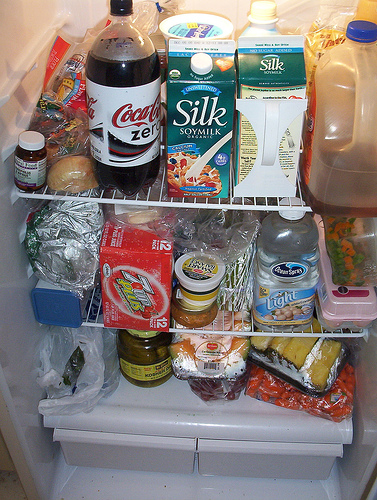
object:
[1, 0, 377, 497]
picture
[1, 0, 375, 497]
fridge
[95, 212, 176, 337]
7 up box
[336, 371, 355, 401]
baby carrot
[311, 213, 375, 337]
egg case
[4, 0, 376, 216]
top rack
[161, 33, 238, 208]
soy milk carton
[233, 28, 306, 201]
soy milk carton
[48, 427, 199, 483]
drawer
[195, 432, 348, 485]
drawer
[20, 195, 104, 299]
foil bag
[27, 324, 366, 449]
bottom rack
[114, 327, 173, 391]
pickle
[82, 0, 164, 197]
coca cola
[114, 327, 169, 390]
jar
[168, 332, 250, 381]
cantaloupe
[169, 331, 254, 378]
package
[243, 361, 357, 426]
bag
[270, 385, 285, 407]
baby carrot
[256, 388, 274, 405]
baby carrot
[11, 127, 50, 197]
bottle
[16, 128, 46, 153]
cap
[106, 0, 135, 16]
cap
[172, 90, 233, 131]
silk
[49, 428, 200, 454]
handle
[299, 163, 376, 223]
tea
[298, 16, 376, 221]
jug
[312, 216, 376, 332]
eggs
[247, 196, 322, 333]
bottle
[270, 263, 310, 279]
oceanspray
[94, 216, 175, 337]
juice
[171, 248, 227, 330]
margarine container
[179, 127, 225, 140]
soy milk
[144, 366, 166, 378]
kosher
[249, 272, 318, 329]
cranberry juice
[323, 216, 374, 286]
mixed vegetables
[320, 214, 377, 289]
bag